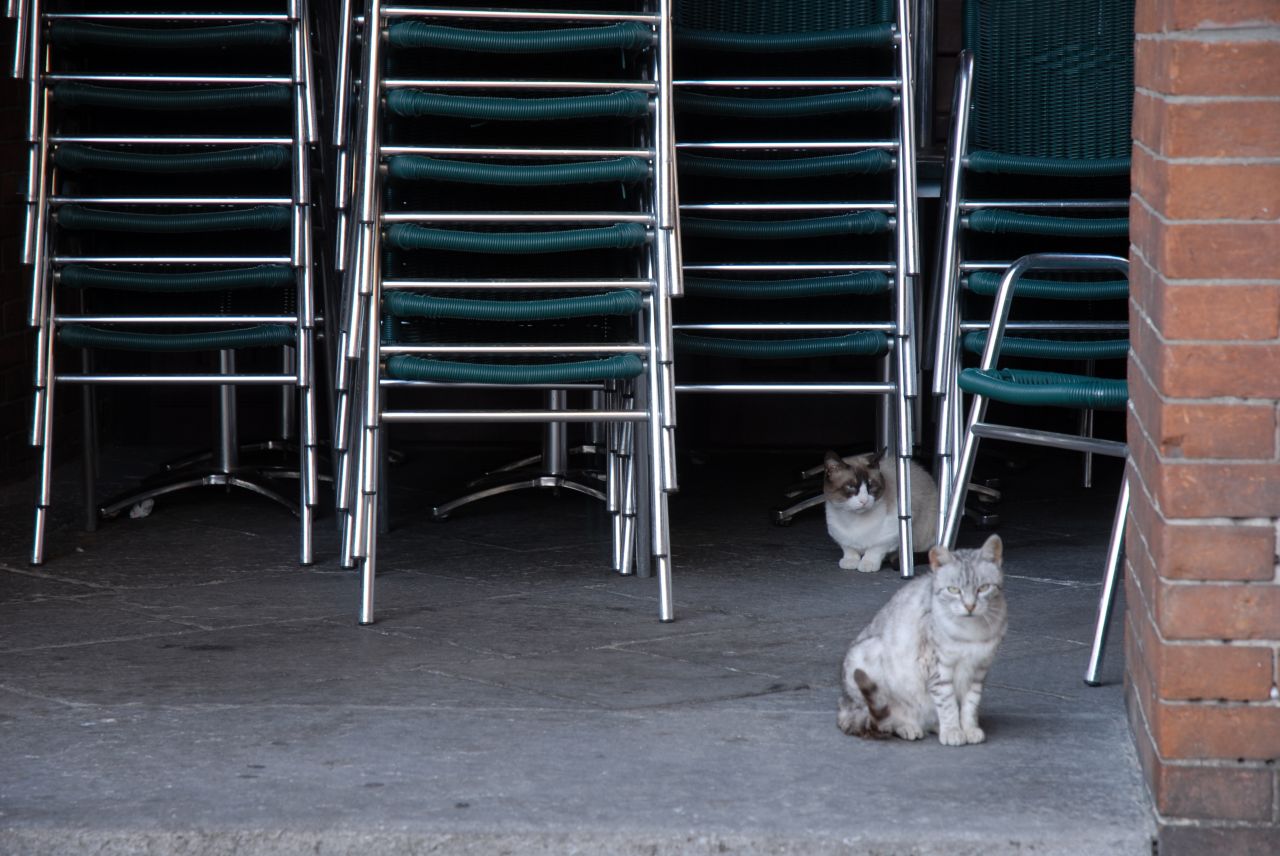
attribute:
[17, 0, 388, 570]
chairs — green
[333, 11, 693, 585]
chairs — green, stacked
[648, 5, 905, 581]
chairs — stacked, green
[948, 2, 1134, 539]
chairs — green, stacked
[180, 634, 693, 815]
concrete floor — grey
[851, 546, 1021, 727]
cat — sitting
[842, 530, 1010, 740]
cat — silver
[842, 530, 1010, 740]
rings — dark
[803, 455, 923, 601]
cat — white, cream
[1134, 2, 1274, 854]
brick — red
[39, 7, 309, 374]
seats — green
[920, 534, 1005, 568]
ears — pointed, silver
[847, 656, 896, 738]
tail — striped, light gray and dark gray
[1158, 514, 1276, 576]
brick — red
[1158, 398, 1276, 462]
brick — red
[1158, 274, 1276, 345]
brick — red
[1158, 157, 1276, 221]
brick — red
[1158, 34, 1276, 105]
brick — red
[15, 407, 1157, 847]
floor — light gray, concrete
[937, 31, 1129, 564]
chair stack — fabric, metal, green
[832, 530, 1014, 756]
white cat — grey markings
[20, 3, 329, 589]
chair stack — metal, green, wicker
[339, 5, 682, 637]
chair stack — silver, metal, green, wicker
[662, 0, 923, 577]
chair stack — green, metal, fabric, green and silver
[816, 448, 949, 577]
crouching cat — under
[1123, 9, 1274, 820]
brick wall — red brick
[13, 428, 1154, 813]
sidewalk — grey, cracked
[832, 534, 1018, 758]
cat — gray, white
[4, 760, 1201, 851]
step — conrete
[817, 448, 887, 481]
ears — dark